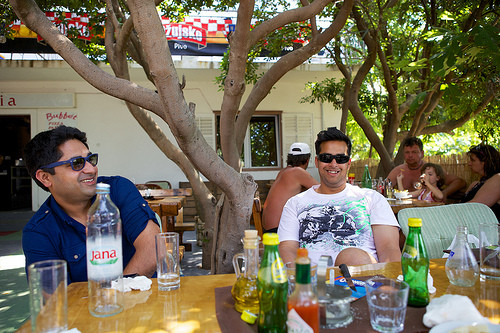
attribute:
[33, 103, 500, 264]
people — sitting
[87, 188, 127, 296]
bottle — empty, water, clear, plastic, tall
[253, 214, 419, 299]
bottles — green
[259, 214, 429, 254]
caps — yellow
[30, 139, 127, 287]
man — sitting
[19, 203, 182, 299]
shirt — blue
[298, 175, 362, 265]
shirt — white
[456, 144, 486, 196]
woman — seated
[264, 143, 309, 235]
man — shirtless, seated, no shirt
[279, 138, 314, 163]
hat — white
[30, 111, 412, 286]
men — sitting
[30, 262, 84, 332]
glass — clear, drinking, tall, empty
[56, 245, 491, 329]
table — wooden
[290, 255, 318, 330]
bottle — glass, hot sauce, tabasco sauce, tabsco sauce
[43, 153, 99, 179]
sunglasses — blue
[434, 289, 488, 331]
napkin — white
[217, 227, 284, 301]
bottle — clear, glass, olive oil, oil, small, cruet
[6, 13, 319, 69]
sign — foreign language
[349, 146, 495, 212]
fence — brown, wooden, picket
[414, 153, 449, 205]
child — drinking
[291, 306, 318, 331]
hot suace — orange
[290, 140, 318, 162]
cap — white, baseball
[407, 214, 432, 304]
bottle — green, glass, clear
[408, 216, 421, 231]
cap — yellow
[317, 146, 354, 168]
sunglasses — black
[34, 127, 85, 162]
hair — black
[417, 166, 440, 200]
girl — little, drinking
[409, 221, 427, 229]
lid — yellow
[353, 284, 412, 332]
tumbler — small, empty